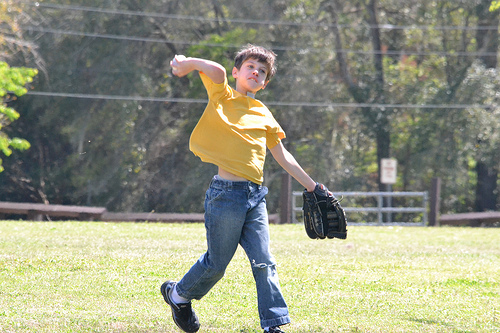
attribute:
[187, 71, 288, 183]
t-shirt — yellow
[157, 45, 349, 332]
boy — white, standing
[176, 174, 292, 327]
blue jeans — torn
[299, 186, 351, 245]
baseball mitt — black, leather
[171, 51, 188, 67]
baseball — white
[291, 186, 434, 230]
gate — metal, silver, large, railing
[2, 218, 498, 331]
grass — green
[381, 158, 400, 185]
sign — white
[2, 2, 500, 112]
lines — power lines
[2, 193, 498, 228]
fence — wood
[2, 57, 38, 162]
leaves — green, bright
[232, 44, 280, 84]
hair — dark, short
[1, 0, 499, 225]
trees — big, green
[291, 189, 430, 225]
railing — metal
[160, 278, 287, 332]
sneakers — sport shoes, black, white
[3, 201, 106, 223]
bench — wooden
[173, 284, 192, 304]
socks — white